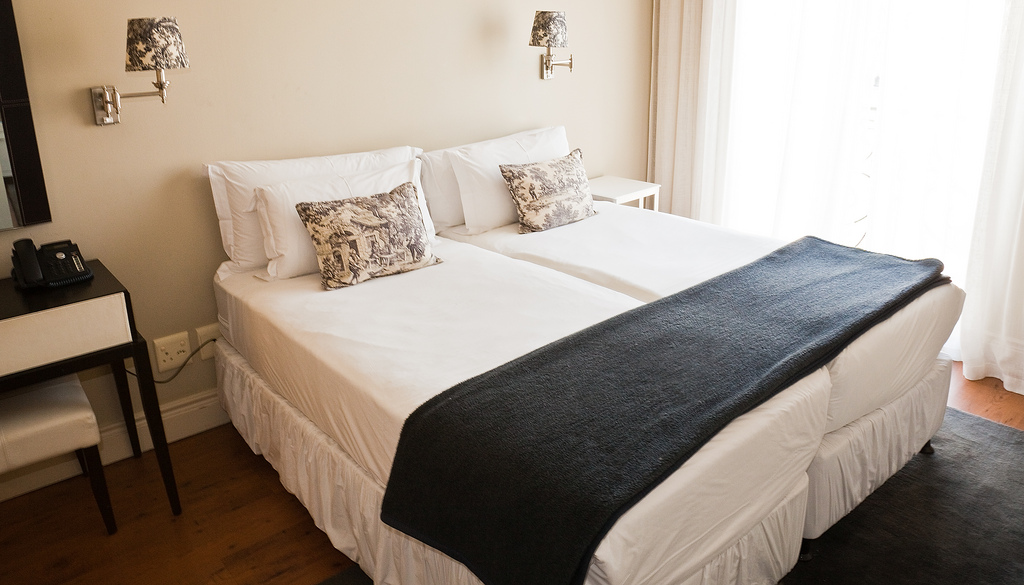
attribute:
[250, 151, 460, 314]
pillow — white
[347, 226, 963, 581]
blanket — black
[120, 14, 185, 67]
lampshade — black, white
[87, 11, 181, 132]
lamp — nickel plated, metal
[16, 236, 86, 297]
telephone — black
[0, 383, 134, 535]
bench — white, rectangular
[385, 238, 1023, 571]
blanket — black, microfleece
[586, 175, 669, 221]
table — small, rectangular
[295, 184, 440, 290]
pillow — black, white, toile print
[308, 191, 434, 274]
pillow — rectangular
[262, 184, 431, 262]
pillow — rectangular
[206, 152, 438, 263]
pillow — rectangular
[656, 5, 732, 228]
curtains — long, white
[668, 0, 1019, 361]
window — sunlit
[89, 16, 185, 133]
lamp — metal, swinging arm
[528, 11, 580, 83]
lamp — metal, swinging arm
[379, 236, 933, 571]
blanket — black